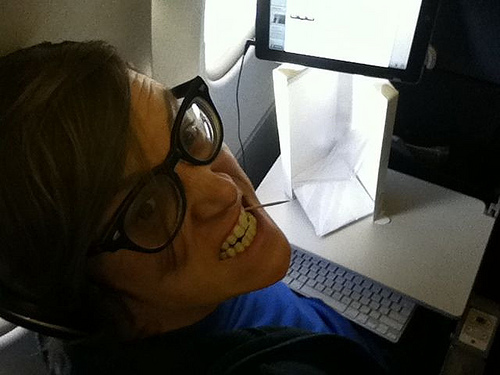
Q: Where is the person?
A: On a plane.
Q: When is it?
A: Day time.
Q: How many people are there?
A: 1.